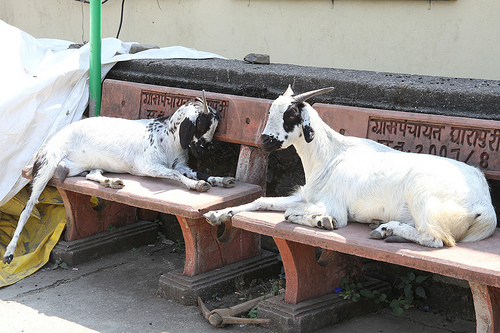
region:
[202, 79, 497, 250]
Black and white goat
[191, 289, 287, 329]
Pick axe lying on the floor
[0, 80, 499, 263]
Two goats sitting on benches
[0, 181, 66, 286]
Yellow tarp lying on the ground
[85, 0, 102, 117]
Green pole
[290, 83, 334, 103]
Antler of goat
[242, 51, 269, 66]
Grey rock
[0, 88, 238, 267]
Black and white goat stretching it's leg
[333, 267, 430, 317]
Weeds underneath a bench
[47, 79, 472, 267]
a bunch of goats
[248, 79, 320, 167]
the head of a small goat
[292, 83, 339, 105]
the horn of a small goat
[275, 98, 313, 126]
the eye of a small goat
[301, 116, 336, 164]
the neck of a small goat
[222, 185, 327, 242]
the front legs of a small goat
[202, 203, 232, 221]
the hoof of a small goat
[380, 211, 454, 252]
the back legs of a small goat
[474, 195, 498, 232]
the tail of a small goat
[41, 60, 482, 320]
two goats sitting on benches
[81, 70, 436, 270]
two black and white goats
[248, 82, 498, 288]
a black and white goat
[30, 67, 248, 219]
a spotted goat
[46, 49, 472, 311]
two goats on a red bench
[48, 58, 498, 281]
a red bench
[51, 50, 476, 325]
a red bench outside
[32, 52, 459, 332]
two goats outside on a bench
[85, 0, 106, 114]
light green pole next to bench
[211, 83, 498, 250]
white goat sitting on banch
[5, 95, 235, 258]
white goat sitting on banch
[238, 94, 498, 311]
red bench with animal sitting on it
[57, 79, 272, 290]
red bench with animal sitting on it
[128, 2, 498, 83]
white wall behind benches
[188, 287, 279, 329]
pick ax laying on floor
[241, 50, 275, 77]
small rock sitting on brick wall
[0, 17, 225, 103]
white tarp style artifact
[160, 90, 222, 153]
animal with white and black face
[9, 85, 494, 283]
two cabros on the scene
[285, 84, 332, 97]
the two horns of the cabro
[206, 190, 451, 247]
the four legs of the cabro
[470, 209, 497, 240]
the tail of the cabro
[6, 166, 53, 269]
an extended leg of the cabro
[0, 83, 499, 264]
two cabros on a bench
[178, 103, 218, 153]
black spots on the cabro head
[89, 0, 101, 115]
a vertical green bar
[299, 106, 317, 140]
one ear of the cabro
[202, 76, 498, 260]
black and white goat on bench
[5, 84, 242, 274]
white and black goat sleeping on bench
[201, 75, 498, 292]
goat relaxing on bench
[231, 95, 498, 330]
stone bench with lettering on back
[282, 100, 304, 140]
black eye of goat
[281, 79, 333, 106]
goat horns atop head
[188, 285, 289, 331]
pick axe between benches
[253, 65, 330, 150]
a goats head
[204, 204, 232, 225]
the goats front right hoof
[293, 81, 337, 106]
the horn of the goat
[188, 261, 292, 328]
a pickaxe on the ground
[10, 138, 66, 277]
the straightened leg of the goat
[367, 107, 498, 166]
writing on the bench behind goat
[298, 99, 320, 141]
the ear of the goat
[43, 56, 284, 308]
the bench the goat in on